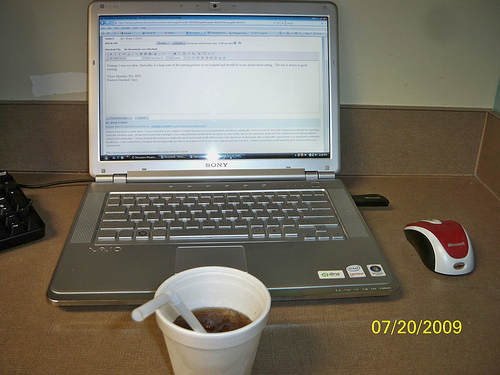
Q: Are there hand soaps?
A: No, there are no hand soaps.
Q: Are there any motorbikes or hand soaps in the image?
A: No, there are no hand soaps or motorbikes.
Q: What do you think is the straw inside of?
A: The straw is inside the cup.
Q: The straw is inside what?
A: The straw is inside the cup.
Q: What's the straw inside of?
A: The straw is inside the cup.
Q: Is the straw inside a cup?
A: Yes, the straw is inside a cup.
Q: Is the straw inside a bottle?
A: No, the straw is inside a cup.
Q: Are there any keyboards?
A: Yes, there is a keyboard.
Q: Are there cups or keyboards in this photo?
A: Yes, there is a keyboard.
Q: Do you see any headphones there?
A: No, there are no headphones.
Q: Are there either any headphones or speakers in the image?
A: No, there are no headphones or speakers.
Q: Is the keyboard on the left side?
A: Yes, the keyboard is on the left of the image.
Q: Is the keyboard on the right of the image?
A: No, the keyboard is on the left of the image.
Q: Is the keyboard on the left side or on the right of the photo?
A: The keyboard is on the left of the image.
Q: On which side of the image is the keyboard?
A: The keyboard is on the left of the image.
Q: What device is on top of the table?
A: The device is a keyboard.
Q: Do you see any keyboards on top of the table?
A: Yes, there is a keyboard on top of the table.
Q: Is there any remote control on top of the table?
A: No, there is a keyboard on top of the table.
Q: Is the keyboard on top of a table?
A: Yes, the keyboard is on top of a table.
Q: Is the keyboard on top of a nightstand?
A: No, the keyboard is on top of a table.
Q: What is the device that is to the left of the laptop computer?
A: The device is a keyboard.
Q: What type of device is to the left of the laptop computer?
A: The device is a keyboard.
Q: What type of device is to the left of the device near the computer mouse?
A: The device is a keyboard.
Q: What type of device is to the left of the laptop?
A: The device is a keyboard.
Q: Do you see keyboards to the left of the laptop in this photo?
A: Yes, there is a keyboard to the left of the laptop.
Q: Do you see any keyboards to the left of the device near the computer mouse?
A: Yes, there is a keyboard to the left of the laptop.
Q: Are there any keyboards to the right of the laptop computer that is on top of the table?
A: No, the keyboard is to the left of the laptop.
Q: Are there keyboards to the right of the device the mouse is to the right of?
A: No, the keyboard is to the left of the laptop.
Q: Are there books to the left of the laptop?
A: No, there is a keyboard to the left of the laptop.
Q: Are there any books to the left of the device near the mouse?
A: No, there is a keyboard to the left of the laptop.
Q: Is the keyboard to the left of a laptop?
A: Yes, the keyboard is to the left of a laptop.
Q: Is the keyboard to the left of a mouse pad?
A: No, the keyboard is to the left of a laptop.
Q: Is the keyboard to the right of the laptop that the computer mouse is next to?
A: No, the keyboard is to the left of the laptop computer.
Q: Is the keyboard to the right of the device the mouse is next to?
A: No, the keyboard is to the left of the laptop computer.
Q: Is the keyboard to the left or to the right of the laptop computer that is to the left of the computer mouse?
A: The keyboard is to the left of the laptop computer.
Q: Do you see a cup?
A: Yes, there is a cup.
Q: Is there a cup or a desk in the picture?
A: Yes, there is a cup.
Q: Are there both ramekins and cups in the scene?
A: No, there is a cup but no ramekins.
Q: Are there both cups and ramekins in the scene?
A: No, there is a cup but no ramekins.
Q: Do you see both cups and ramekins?
A: No, there is a cup but no ramekins.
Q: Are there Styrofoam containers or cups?
A: Yes, there is a Styrofoam cup.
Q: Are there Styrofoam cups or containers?
A: Yes, there is a Styrofoam cup.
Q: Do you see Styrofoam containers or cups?
A: Yes, there is a Styrofoam cup.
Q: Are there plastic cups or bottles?
A: Yes, there is a plastic cup.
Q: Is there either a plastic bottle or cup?
A: Yes, there is a plastic cup.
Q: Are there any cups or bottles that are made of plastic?
A: Yes, the cup is made of plastic.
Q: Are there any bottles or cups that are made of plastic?
A: Yes, the cup is made of plastic.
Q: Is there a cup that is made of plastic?
A: Yes, there is a cup that is made of plastic.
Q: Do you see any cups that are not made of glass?
A: Yes, there is a cup that is made of plastic.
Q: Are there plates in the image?
A: No, there are no plates.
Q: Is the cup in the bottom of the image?
A: Yes, the cup is in the bottom of the image.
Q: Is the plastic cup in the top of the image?
A: No, the cup is in the bottom of the image.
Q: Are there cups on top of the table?
A: Yes, there is a cup on top of the table.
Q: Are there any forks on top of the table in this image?
A: No, there is a cup on top of the table.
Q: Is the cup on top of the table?
A: Yes, the cup is on top of the table.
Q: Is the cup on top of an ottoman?
A: No, the cup is on top of the table.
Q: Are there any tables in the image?
A: Yes, there is a table.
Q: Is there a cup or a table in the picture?
A: Yes, there is a table.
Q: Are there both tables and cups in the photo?
A: Yes, there are both a table and a cup.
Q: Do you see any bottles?
A: No, there are no bottles.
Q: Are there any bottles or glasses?
A: No, there are no bottles or glasses.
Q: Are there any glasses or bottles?
A: No, there are no bottles or glasses.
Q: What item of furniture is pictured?
A: The piece of furniture is a table.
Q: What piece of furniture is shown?
A: The piece of furniture is a table.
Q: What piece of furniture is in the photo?
A: The piece of furniture is a table.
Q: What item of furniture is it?
A: The piece of furniture is a table.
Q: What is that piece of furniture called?
A: This is a table.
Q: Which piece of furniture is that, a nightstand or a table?
A: This is a table.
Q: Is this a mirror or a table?
A: This is a table.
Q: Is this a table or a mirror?
A: This is a table.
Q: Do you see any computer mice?
A: Yes, there is a computer mouse.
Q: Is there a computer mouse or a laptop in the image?
A: Yes, there is a computer mouse.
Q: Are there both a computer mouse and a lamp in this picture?
A: No, there is a computer mouse but no lamps.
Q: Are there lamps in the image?
A: No, there are no lamps.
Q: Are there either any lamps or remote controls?
A: No, there are no lamps or remote controls.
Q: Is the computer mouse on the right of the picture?
A: Yes, the computer mouse is on the right of the image.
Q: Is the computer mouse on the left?
A: No, the computer mouse is on the right of the image.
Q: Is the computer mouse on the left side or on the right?
A: The computer mouse is on the right of the image.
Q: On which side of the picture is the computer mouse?
A: The computer mouse is on the right of the image.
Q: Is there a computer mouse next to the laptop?
A: Yes, there is a computer mouse next to the laptop.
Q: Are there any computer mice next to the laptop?
A: Yes, there is a computer mouse next to the laptop.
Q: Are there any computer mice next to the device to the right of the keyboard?
A: Yes, there is a computer mouse next to the laptop.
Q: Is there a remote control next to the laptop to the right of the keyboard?
A: No, there is a computer mouse next to the laptop.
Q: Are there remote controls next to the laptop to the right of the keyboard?
A: No, there is a computer mouse next to the laptop.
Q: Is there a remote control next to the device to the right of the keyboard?
A: No, there is a computer mouse next to the laptop.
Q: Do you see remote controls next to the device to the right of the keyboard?
A: No, there is a computer mouse next to the laptop.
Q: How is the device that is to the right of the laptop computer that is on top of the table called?
A: The device is a computer mouse.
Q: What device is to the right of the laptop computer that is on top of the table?
A: The device is a computer mouse.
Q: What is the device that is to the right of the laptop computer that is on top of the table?
A: The device is a computer mouse.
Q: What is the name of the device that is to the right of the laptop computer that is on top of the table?
A: The device is a computer mouse.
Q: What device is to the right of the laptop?
A: The device is a computer mouse.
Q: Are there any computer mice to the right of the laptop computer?
A: Yes, there is a computer mouse to the right of the laptop computer.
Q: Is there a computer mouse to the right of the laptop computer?
A: Yes, there is a computer mouse to the right of the laptop computer.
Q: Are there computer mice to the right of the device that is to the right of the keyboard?
A: Yes, there is a computer mouse to the right of the laptop computer.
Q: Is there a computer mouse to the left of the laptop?
A: No, the computer mouse is to the right of the laptop.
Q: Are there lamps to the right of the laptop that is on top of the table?
A: No, there is a computer mouse to the right of the laptop.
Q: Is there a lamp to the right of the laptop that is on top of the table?
A: No, there is a computer mouse to the right of the laptop.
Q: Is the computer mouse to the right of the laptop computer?
A: Yes, the computer mouse is to the right of the laptop computer.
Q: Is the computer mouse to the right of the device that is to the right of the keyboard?
A: Yes, the computer mouse is to the right of the laptop computer.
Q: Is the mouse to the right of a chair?
A: No, the mouse is to the right of the laptop computer.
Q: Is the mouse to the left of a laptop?
A: No, the mouse is to the right of a laptop.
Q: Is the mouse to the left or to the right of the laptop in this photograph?
A: The mouse is to the right of the laptop.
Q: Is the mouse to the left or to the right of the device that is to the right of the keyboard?
A: The mouse is to the right of the laptop.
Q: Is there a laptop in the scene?
A: Yes, there is a laptop.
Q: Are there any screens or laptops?
A: Yes, there is a laptop.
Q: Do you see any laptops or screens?
A: Yes, there is a laptop.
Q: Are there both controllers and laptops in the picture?
A: No, there is a laptop but no controllers.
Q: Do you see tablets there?
A: No, there are no tablets.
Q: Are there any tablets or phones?
A: No, there are no tablets or phones.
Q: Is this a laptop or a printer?
A: This is a laptop.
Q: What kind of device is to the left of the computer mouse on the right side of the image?
A: The device is a laptop.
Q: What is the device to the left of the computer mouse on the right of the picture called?
A: The device is a laptop.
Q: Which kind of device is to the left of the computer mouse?
A: The device is a laptop.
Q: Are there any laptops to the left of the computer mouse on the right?
A: Yes, there is a laptop to the left of the mouse.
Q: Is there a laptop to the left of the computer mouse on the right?
A: Yes, there is a laptop to the left of the mouse.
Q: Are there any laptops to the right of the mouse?
A: No, the laptop is to the left of the mouse.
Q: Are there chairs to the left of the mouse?
A: No, there is a laptop to the left of the mouse.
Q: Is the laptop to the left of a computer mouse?
A: Yes, the laptop is to the left of a computer mouse.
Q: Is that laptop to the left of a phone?
A: No, the laptop is to the left of a computer mouse.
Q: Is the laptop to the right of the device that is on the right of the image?
A: No, the laptop is to the left of the mouse.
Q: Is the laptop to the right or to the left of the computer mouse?
A: The laptop is to the left of the computer mouse.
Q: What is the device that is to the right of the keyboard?
A: The device is a laptop.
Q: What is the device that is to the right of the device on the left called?
A: The device is a laptop.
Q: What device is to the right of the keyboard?
A: The device is a laptop.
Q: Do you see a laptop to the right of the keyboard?
A: Yes, there is a laptop to the right of the keyboard.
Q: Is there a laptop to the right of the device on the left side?
A: Yes, there is a laptop to the right of the keyboard.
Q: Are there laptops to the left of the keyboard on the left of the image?
A: No, the laptop is to the right of the keyboard.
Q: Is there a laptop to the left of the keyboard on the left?
A: No, the laptop is to the right of the keyboard.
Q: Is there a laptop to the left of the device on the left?
A: No, the laptop is to the right of the keyboard.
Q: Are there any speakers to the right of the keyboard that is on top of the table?
A: No, there is a laptop to the right of the keyboard.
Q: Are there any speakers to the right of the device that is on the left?
A: No, there is a laptop to the right of the keyboard.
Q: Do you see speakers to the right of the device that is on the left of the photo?
A: No, there is a laptop to the right of the keyboard.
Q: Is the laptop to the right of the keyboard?
A: Yes, the laptop is to the right of the keyboard.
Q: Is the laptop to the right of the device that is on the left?
A: Yes, the laptop is to the right of the keyboard.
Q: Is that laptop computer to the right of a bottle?
A: No, the laptop computer is to the right of the keyboard.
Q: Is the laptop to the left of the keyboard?
A: No, the laptop is to the right of the keyboard.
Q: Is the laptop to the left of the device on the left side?
A: No, the laptop is to the right of the keyboard.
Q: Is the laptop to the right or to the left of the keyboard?
A: The laptop is to the right of the keyboard.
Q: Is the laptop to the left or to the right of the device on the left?
A: The laptop is to the right of the keyboard.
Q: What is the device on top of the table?
A: The device is a laptop.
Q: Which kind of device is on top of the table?
A: The device is a laptop.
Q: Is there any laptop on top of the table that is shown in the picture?
A: Yes, there is a laptop on top of the table.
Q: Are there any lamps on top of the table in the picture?
A: No, there is a laptop on top of the table.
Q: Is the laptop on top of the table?
A: Yes, the laptop is on top of the table.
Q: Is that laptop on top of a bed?
A: No, the laptop is on top of the table.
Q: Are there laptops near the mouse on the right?
A: Yes, there is a laptop near the computer mouse.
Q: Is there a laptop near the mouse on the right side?
A: Yes, there is a laptop near the computer mouse.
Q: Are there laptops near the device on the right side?
A: Yes, there is a laptop near the computer mouse.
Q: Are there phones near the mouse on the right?
A: No, there is a laptop near the mouse.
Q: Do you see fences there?
A: No, there are no fences.